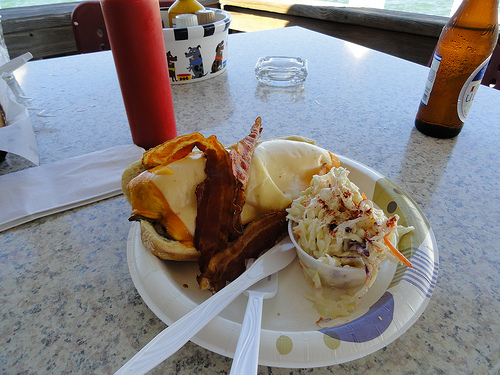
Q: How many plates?
A: 1.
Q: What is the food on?
A: Plate.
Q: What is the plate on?
A: Table.